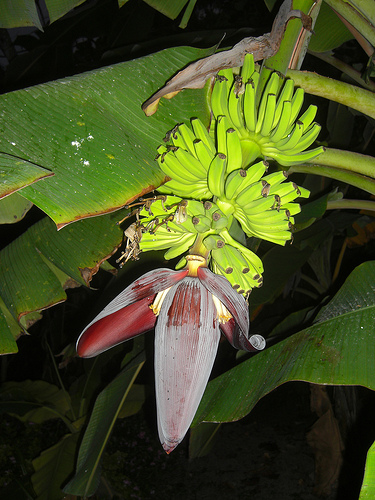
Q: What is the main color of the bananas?
A: Green.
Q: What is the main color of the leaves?
A: Red.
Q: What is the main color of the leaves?
A: Green.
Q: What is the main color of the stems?
A: Green.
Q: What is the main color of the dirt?
A: Brown.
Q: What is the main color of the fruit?
A: Green.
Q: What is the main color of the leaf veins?
A: Green.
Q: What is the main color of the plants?
A: Green.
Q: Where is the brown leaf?
A: On the tree.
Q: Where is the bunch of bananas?
A: On the tree.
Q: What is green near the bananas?
A: The leaves.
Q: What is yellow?
A: Bananas.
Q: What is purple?
A: The flower.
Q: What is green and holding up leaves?
A: Stems.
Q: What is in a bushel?
A: Bananas.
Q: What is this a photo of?
A: Tropical fruit.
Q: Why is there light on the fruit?
A: Camera flash created light.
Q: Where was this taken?
A: The tropics.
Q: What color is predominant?
A: Green.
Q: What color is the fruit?
A: Yellow-green.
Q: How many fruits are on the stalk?
A: At least 63.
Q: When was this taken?
A: At night.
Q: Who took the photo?
A: A photographer.